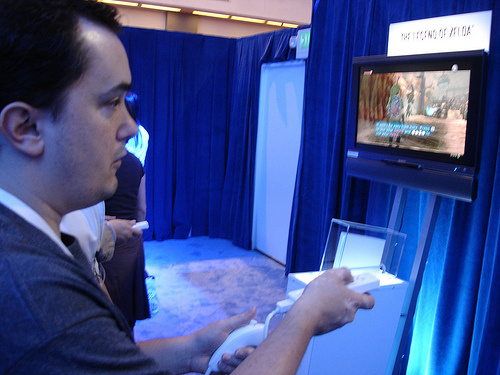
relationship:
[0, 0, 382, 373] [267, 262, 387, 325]
guy holding controller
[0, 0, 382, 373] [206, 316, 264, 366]
guy holding nunchuck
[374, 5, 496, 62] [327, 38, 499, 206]
sign above flat screen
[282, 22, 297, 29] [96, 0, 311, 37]
light on ceiling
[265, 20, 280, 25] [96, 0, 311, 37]
light on ceiling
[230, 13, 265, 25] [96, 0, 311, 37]
light on ceiling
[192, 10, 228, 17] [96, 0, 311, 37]
light on ceiling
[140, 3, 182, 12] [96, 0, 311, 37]
light on ceiling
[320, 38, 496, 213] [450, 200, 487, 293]
television in front of drapes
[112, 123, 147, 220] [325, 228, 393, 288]
back to wii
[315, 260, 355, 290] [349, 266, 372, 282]
thumb on button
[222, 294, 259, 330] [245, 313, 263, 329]
thumb on button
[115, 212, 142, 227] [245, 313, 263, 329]
thumb on button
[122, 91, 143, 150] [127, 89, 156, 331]
hair on woman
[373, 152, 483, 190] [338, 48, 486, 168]
buttons on television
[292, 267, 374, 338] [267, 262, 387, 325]
hand holding controller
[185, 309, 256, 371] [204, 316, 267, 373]
hand holding nunchuck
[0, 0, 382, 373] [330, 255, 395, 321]
guy playing wii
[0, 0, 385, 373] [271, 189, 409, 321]
guy playing game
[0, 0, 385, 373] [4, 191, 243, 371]
guy wearing shirt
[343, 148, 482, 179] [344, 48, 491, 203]
sensor bar attached to television